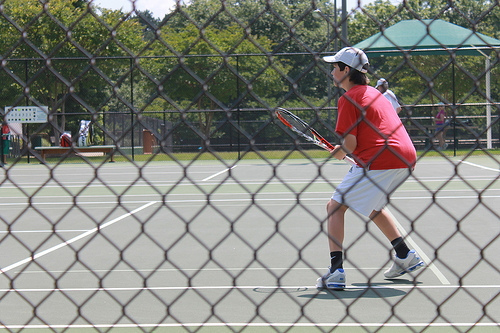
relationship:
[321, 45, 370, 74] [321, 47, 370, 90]
cap on head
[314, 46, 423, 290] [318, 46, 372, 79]
man wearing cap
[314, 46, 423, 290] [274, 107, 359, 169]
man holding racket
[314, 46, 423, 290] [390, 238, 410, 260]
man wearing black socks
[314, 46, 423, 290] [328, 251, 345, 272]
man wearing black socks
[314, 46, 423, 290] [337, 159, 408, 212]
man wearing shorts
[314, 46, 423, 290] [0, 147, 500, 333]
man on court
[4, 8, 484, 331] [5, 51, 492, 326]
fence around tennis court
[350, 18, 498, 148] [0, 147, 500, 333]
tent behind court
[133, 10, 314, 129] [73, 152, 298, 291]
trees behind court